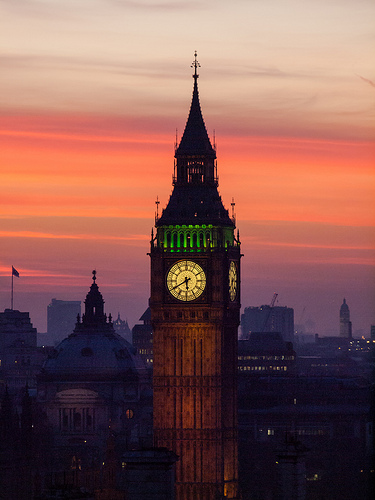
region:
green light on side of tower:
[155, 222, 225, 257]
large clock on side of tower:
[155, 255, 214, 307]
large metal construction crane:
[260, 291, 285, 331]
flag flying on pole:
[9, 261, 19, 277]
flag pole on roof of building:
[4, 276, 23, 306]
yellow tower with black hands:
[157, 254, 215, 305]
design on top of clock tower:
[176, 40, 210, 84]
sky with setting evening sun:
[5, 128, 124, 248]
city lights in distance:
[335, 324, 374, 356]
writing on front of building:
[56, 391, 98, 399]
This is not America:
[31, 40, 336, 478]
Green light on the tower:
[145, 196, 245, 269]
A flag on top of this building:
[7, 255, 41, 337]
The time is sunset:
[23, 90, 365, 311]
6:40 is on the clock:
[156, 251, 213, 311]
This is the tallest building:
[154, 36, 248, 493]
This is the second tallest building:
[35, 241, 153, 414]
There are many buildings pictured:
[10, 244, 361, 454]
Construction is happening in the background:
[242, 267, 298, 350]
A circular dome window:
[20, 308, 173, 392]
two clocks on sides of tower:
[151, 259, 240, 303]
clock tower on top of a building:
[145, 47, 244, 444]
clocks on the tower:
[165, 259, 237, 301]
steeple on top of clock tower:
[173, 50, 215, 153]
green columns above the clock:
[163, 229, 212, 248]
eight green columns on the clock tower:
[162, 230, 213, 250]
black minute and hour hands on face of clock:
[173, 276, 190, 289]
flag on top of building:
[8, 266, 19, 308]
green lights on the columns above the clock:
[161, 224, 235, 251]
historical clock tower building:
[146, 49, 244, 444]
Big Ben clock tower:
[142, 47, 252, 491]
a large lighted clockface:
[164, 259, 208, 304]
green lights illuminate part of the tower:
[157, 224, 235, 251]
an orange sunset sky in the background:
[0, 108, 374, 301]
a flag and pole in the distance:
[8, 263, 21, 310]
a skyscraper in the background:
[338, 298, 352, 341]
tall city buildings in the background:
[4, 267, 374, 401]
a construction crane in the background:
[258, 289, 280, 329]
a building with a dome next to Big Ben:
[45, 266, 151, 457]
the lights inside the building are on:
[235, 350, 295, 375]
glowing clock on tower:
[162, 254, 210, 307]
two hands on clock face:
[168, 274, 198, 294]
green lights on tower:
[155, 220, 218, 257]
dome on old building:
[43, 324, 145, 392]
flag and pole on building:
[4, 259, 27, 321]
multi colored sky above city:
[250, 128, 357, 356]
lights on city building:
[238, 346, 299, 379]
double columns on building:
[47, 399, 105, 441]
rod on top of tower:
[184, 44, 209, 86]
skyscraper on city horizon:
[332, 292, 357, 340]